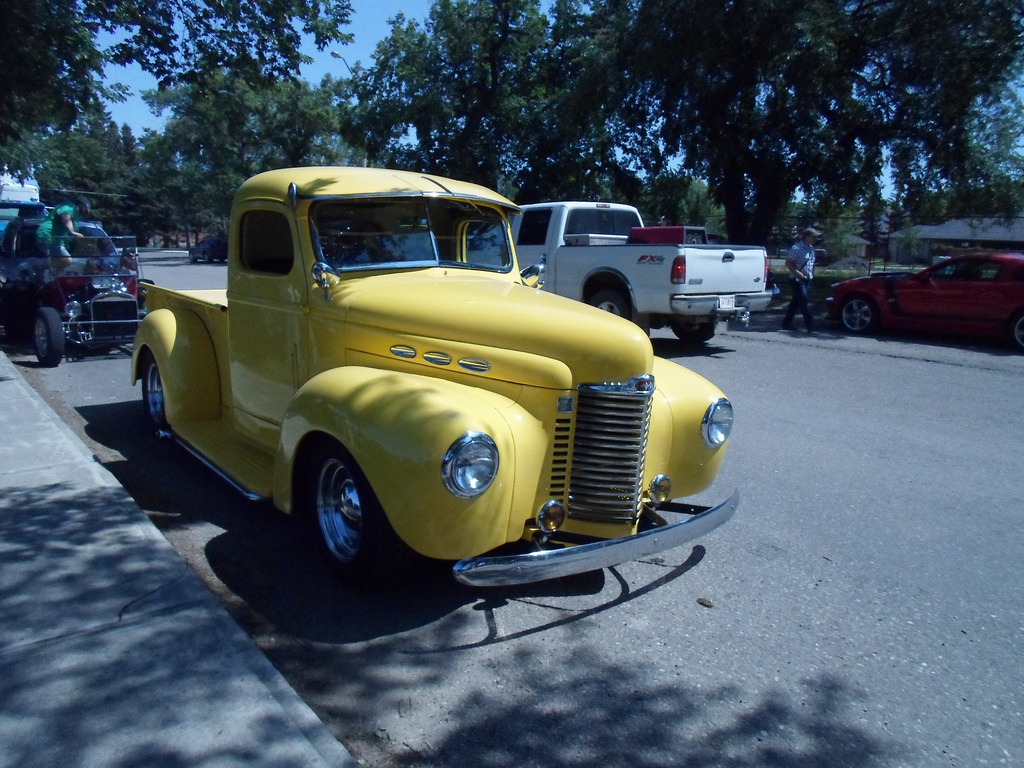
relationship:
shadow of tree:
[6, 474, 897, 764] [0, 1, 359, 192]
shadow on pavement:
[6, 474, 897, 764] [2, 255, 977, 765]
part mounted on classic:
[448, 487, 742, 589] [129, 163, 746, 597]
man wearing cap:
[781, 224, 824, 338] [795, 196, 845, 251]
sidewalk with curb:
[26, 401, 264, 764] [145, 505, 314, 763]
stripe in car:
[871, 286, 1010, 334] [864, 233, 1020, 350]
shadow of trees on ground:
[0, 474, 918, 768] [501, 628, 865, 768]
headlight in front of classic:
[452, 434, 504, 499] [129, 163, 746, 597]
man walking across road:
[758, 200, 849, 371] [761, 298, 962, 420]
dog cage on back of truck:
[624, 200, 724, 255] [549, 207, 766, 322]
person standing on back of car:
[15, 185, 117, 432] [0, 201, 157, 371]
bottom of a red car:
[877, 302, 1022, 344] [828, 250, 1024, 353]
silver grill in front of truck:
[577, 375, 662, 546] [195, 311, 731, 616]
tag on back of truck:
[717, 304, 750, 317] [607, 216, 791, 327]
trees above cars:
[35, 103, 893, 149] [681, 233, 965, 277]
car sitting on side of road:
[164, 198, 236, 272] [123, 235, 932, 300]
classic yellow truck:
[106, 205, 729, 620] [363, 397, 538, 458]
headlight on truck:
[437, 429, 502, 503] [195, 347, 747, 665]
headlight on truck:
[674, 405, 754, 488] [168, 308, 741, 641]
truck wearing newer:
[599, 185, 801, 345] [694, 274, 733, 281]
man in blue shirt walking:
[781, 224, 824, 338] [771, 310, 867, 350]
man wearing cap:
[781, 224, 824, 338] [796, 221, 823, 239]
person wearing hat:
[32, 193, 91, 279] [57, 201, 77, 212]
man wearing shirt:
[781, 224, 824, 338] [783, 245, 827, 276]